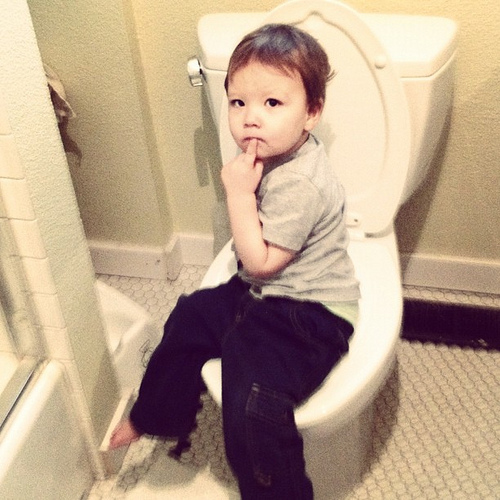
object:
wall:
[19, 0, 499, 273]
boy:
[104, 13, 363, 499]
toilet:
[182, 2, 464, 498]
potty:
[92, 262, 161, 374]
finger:
[242, 129, 262, 163]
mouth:
[240, 132, 268, 146]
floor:
[384, 356, 500, 498]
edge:
[2, 220, 50, 418]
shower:
[0, 0, 109, 498]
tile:
[0, 0, 112, 426]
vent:
[402, 290, 500, 355]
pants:
[122, 278, 359, 500]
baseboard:
[404, 249, 499, 298]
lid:
[317, 4, 419, 238]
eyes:
[227, 92, 289, 110]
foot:
[100, 407, 144, 455]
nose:
[242, 101, 263, 129]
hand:
[216, 137, 267, 198]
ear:
[301, 90, 329, 133]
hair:
[223, 19, 338, 115]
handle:
[181, 52, 210, 95]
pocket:
[284, 298, 349, 349]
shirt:
[227, 139, 367, 324]